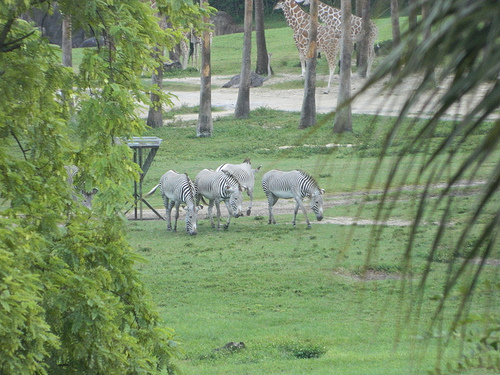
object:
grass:
[199, 326, 442, 371]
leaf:
[398, 0, 500, 88]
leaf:
[0, 141, 57, 215]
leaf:
[439, 314, 499, 354]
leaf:
[1, 279, 117, 351]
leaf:
[426, 151, 496, 252]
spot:
[319, 39, 324, 45]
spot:
[330, 44, 336, 52]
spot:
[330, 30, 338, 40]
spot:
[301, 28, 309, 38]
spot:
[292, 5, 302, 13]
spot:
[354, 16, 362, 27]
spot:
[352, 15, 360, 24]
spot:
[331, 8, 341, 13]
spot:
[327, 6, 333, 14]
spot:
[327, 27, 333, 30]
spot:
[293, 8, 306, 18]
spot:
[295, 17, 305, 24]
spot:
[317, 24, 328, 32]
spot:
[327, 16, 338, 24]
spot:
[327, 47, 333, 57]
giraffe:
[281, 0, 354, 94]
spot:
[327, 5, 332, 13]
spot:
[333, 5, 341, 15]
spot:
[316, 11, 324, 16]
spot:
[328, 19, 338, 28]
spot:
[347, 13, 355, 22]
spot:
[316, 6, 325, 14]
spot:
[320, 10, 330, 19]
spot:
[325, 8, 335, 16]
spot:
[333, 6, 339, 14]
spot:
[357, 16, 362, 29]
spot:
[298, 33, 307, 45]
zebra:
[261, 168, 325, 230]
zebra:
[194, 168, 247, 231]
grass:
[334, 216, 482, 242]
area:
[156, 239, 321, 330]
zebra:
[216, 158, 263, 216]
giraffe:
[273, 0, 306, 77]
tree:
[332, 0, 353, 136]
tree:
[297, 0, 317, 130]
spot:
[289, 9, 298, 24]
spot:
[320, 9, 328, 22]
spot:
[326, 41, 340, 47]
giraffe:
[282, 0, 343, 94]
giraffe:
[301, 0, 378, 78]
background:
[140, 1, 466, 131]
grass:
[160, 234, 225, 249]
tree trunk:
[232, 0, 254, 120]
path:
[81, 179, 489, 220]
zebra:
[142, 170, 203, 236]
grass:
[115, 279, 495, 308]